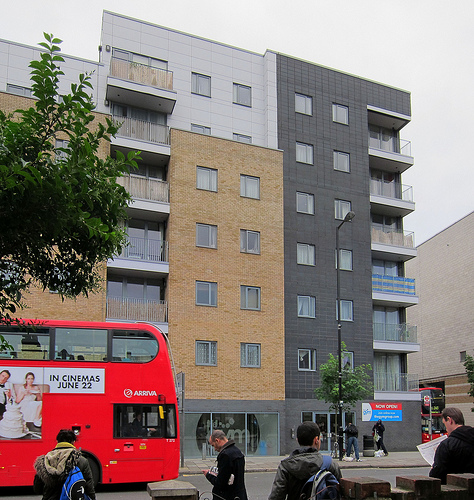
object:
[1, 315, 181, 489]
bus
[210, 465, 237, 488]
news paper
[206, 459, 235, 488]
arm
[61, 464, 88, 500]
backpack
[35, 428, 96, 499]
mans shoulder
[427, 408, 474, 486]
man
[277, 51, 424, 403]
apartment building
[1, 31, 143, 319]
trees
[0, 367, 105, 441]
advertisement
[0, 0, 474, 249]
sky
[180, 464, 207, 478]
curb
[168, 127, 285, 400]
brown building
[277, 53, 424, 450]
building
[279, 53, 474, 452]
corner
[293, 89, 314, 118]
windows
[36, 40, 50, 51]
green leaves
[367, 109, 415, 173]
apartment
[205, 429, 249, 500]
man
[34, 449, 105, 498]
jacket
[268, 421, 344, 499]
man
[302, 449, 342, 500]
grey backpack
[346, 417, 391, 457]
pedestrians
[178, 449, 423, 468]
walkway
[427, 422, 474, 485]
black jacket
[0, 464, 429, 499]
street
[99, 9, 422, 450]
building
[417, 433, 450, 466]
newspaper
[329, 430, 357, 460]
bicycle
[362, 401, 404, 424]
advertising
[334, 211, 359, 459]
street light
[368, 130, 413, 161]
railing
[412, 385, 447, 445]
bus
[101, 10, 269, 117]
apartment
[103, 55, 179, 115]
balcony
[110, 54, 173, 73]
railing